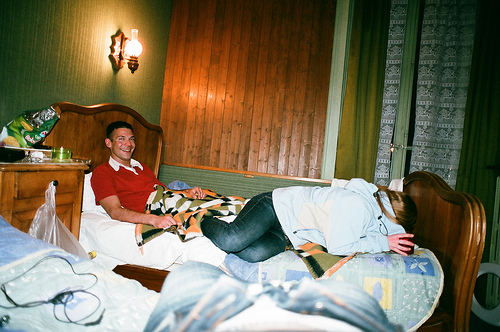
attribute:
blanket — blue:
[228, 246, 443, 324]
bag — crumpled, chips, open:
[4, 108, 56, 146]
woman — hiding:
[206, 183, 415, 259]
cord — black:
[7, 257, 109, 324]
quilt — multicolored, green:
[146, 188, 242, 246]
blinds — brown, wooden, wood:
[171, 7, 331, 175]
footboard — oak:
[410, 173, 485, 332]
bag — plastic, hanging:
[36, 184, 82, 259]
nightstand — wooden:
[6, 159, 88, 253]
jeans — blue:
[196, 193, 289, 263]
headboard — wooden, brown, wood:
[51, 103, 162, 172]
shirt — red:
[91, 165, 170, 210]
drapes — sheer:
[373, 3, 470, 193]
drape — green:
[336, 0, 382, 182]